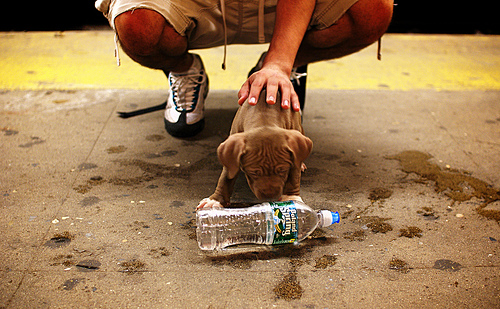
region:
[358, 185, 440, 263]
small green shrubbery on the ground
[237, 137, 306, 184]
wrinkles on dog's face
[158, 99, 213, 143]
black lining on white sneakers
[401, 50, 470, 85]
yellow color on the ground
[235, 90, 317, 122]
well manicured finger nails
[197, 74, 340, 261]
Puppy sniffing a water bottle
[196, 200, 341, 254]
Plastic water bottle on the ground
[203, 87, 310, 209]
Little brown puppy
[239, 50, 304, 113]
Man's hand on the puppy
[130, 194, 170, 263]
Puppy footprints on the ground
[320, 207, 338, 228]
Cap on water bottle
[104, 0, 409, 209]
Man and a puppy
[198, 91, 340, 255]
Puppy sniffing a plastic water bottle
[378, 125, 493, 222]
Wet spot on the concrete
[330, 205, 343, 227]
Cap on a bottle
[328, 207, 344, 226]
Cap on a water bottle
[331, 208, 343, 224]
Blue cap on a water bottle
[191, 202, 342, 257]
Bottle on it's side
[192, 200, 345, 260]
Water bottle on it's side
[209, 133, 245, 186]
Ear of a dog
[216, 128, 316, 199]
Head of a dog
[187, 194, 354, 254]
Clear plastic water bottle.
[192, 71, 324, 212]
Small wrinkled puppy sniffing water bottle.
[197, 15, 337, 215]
Man with hand on puppy.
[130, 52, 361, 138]
Man wearing black and white shoes.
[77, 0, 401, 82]
Man wearing light colored shorts.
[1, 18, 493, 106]
Yellow stripe on cement.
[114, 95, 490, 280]
Water on different spots on cement.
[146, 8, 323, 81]
Man has ties on his shorts.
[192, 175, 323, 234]
Puppy has white paws.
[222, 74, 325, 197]
small brown puppy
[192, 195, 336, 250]
water bottle on the ground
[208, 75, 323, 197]
puppy has wrinkles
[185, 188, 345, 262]
water bottle has green lable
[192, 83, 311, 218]
puppy has white paw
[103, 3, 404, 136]
man is wearing tan cargo shorts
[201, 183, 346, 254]
Bottle on it's side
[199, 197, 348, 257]
Bottle on the ground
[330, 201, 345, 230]
Cap on a water bottle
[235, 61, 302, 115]
the hand of a young man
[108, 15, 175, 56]
the knee of a young man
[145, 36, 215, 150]
the shoe of a young man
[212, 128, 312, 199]
the head of a young puppy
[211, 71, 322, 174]
A hand touching a dog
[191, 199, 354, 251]
A tipped over water bottle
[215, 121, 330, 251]
A dog sniffing a water bottle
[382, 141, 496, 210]
a small puddle of water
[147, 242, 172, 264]
A paw print from a little dog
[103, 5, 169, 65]
the knee of a man who is squatting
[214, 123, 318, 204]
The wrinkled face of a puppy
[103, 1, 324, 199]
A man touching the back end of a dog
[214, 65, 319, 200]
A hand touching a little brown puppy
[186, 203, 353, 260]
a Water bottle on the sidewalk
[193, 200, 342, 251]
plastic water bottle on ground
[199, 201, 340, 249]
plastic bottle in front of puppy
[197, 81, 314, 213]
puppy behind plastic bottle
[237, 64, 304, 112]
hand holding brown puppy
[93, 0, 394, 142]
person squatting behind puppy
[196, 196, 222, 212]
puppy has white paw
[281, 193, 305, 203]
puppy has white paw